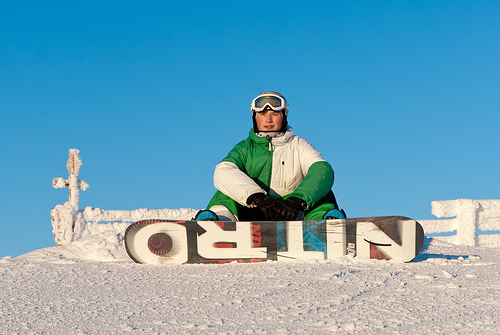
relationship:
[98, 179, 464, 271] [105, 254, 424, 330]
fence covered in snow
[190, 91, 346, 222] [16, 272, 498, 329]
person sitting in snow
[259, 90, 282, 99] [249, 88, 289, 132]
tan helmet on head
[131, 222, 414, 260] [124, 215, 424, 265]
letters on colored snowboard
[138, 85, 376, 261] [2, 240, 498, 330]
person sitting on hill